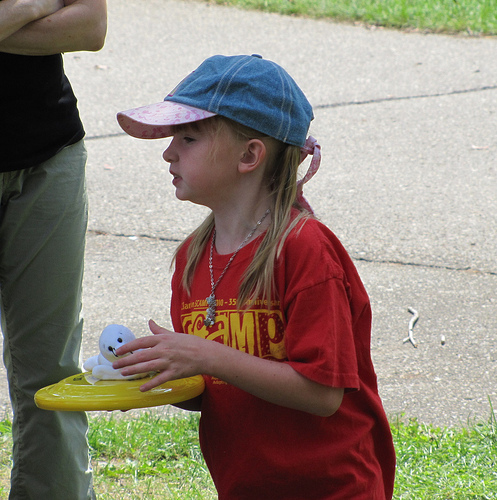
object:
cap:
[116, 54, 321, 215]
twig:
[397, 304, 422, 351]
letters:
[174, 296, 285, 385]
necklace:
[203, 202, 274, 330]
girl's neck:
[210, 185, 270, 242]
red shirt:
[172, 194, 401, 499]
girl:
[111, 53, 396, 498]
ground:
[0, 0, 497, 499]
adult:
[0, 1, 109, 500]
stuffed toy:
[84, 323, 150, 379]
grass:
[0, 406, 496, 499]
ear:
[236, 139, 266, 173]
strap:
[297, 136, 322, 214]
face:
[99, 324, 140, 363]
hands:
[112, 317, 199, 392]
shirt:
[0, 49, 85, 172]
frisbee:
[34, 372, 207, 410]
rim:
[116, 100, 216, 139]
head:
[161, 53, 313, 207]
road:
[0, 1, 495, 428]